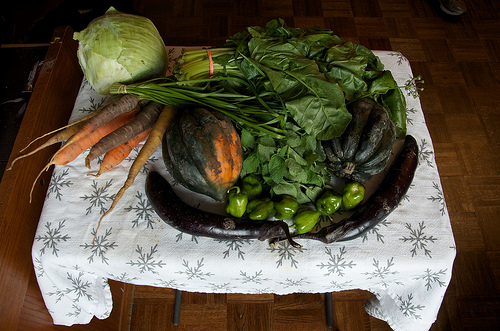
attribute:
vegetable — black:
[163, 153, 273, 249]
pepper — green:
[344, 180, 366, 208]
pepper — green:
[314, 193, 346, 217]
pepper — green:
[293, 207, 321, 235]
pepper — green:
[246, 201, 273, 218]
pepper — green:
[227, 182, 249, 216]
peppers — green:
[340, 180, 366, 211]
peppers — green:
[229, 192, 315, 239]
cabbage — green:
[68, 8, 170, 92]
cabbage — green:
[65, 14, 173, 94]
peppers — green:
[289, 208, 318, 232]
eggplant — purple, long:
[322, 139, 419, 248]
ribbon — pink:
[206, 48, 218, 70]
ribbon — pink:
[198, 42, 219, 82]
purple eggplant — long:
[301, 129, 423, 234]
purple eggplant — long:
[137, 170, 292, 245]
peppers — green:
[224, 177, 369, 234]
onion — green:
[105, 72, 295, 137]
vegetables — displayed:
[72, 14, 418, 242]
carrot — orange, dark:
[29, 97, 149, 197]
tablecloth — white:
[31, 50, 457, 330]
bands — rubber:
[114, 80, 126, 95]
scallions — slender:
[104, 72, 295, 136]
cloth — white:
[11, 184, 233, 275]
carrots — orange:
[12, 92, 170, 223]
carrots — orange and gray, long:
[9, 95, 174, 236]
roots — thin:
[13, 117, 130, 245]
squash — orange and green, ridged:
[162, 105, 240, 198]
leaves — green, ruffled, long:
[213, 54, 413, 209]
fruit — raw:
[16, 5, 420, 250]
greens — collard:
[206, 19, 402, 224]